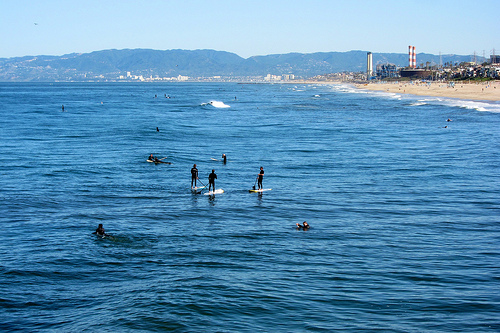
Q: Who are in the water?
A: Surfers.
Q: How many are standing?
A: Three.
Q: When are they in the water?
A: During the day.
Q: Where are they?
A: In the ocean.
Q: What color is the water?
A: Blue.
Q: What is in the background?
A: Mountains.